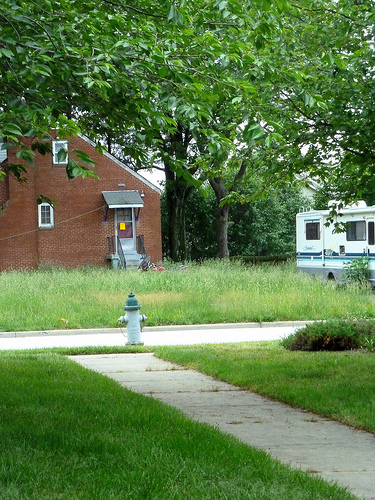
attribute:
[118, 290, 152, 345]
fire hydrant — green, blue, white, gray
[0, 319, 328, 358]
road — left to right, narrow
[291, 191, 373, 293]
rv — white, blue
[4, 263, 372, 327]
grass — yard, weeds, green, tall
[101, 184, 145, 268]
door — screen door, white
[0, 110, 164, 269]
building — brick, red, 2 story, brown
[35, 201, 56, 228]
window — white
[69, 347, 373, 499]
sidewalk — white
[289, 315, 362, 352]
bush — green, brown, low lying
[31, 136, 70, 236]
windows — white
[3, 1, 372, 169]
leaves — green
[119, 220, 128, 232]
note — yellow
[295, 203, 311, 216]
ladder — metal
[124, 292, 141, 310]
top — dark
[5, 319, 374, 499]
yard — green, grass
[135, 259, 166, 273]
motorcycle — red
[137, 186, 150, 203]
light — porch light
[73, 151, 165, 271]
wall — brick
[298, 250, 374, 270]
lines — blue